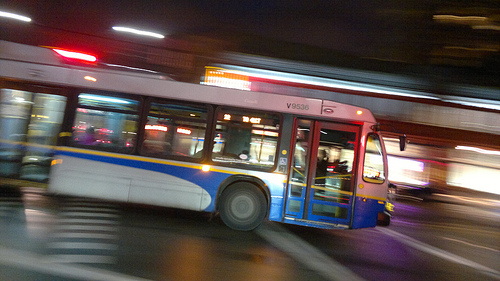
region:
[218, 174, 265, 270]
part of a wheel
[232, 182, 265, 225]
part of a wheel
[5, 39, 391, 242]
bus traveling down street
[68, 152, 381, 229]
blue stripe on white bus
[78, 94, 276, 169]
windows on side of bus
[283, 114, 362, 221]
doors of the white bus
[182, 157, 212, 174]
glare of light on side of bus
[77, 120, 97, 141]
person sitting on bus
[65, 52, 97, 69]
glowing red light above bus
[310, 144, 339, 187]
driver of blue and white bus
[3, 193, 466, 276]
white lines painted on street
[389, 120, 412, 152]
side view mirror of bus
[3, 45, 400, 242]
a city bus is moving into an intersection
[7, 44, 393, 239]
the bus is white with blue trim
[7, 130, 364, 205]
a yellow stripe is down the side of the bus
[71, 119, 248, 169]
people are sitting on the bus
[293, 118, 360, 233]
the door of the bus is closed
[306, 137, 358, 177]
the driver has his hands on the steering wheel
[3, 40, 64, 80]
the air conditioning unit is on the bus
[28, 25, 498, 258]
the bus is near an overpass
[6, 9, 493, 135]
the lights are lit on the overpass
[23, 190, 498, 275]
the intersection has white painted lines on the road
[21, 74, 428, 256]
bus on the street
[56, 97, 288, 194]
windows on the bus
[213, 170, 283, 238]
tire on the bus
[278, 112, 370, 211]
door of the bus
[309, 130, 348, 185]
driver in the bus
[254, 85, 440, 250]
front of the bus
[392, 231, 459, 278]
white line on the street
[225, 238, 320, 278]
street next to the bus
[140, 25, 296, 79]
blurry background of the photo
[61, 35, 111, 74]
red light in the photo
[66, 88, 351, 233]
this is a bus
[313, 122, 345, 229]
this is the door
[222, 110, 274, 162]
this is the window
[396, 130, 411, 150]
this is a side mirror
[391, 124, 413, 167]
the mirror is black in color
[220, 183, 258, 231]
this is the wheel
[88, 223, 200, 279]
this is the road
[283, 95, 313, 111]
this is a writing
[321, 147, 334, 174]
this is the driver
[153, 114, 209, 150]
the glass is transparent